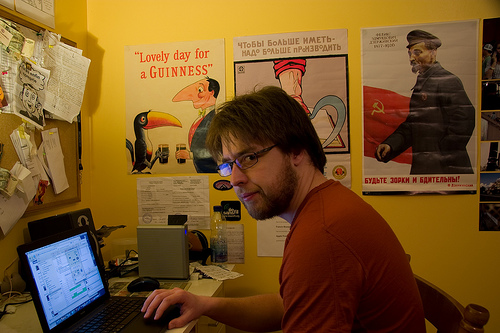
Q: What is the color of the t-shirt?
A: Orange.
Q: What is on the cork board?
A: Papers.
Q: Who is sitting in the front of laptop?
A: The man.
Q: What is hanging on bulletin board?
A: Papers.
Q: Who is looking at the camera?
A: A man.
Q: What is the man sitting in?
A: In a chair.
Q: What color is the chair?
A: Brown.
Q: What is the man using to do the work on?
A: Laptop.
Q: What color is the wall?
A: Yellow.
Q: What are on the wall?
A: Posters.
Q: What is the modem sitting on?
A: The desk.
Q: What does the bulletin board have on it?
A: Papers.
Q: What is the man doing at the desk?
A: Working.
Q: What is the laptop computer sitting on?
A: The desk.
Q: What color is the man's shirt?
A: Red.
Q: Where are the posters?
A: On the walls.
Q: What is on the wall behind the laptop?
A: A cork board.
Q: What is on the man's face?
A: Glasses.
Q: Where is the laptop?
A: On the desk.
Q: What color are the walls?
A: Yellow.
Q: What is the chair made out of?
A: Wood.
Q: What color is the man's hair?
A: Brown.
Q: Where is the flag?
A: On the poster.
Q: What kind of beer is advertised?
A: Guinness.